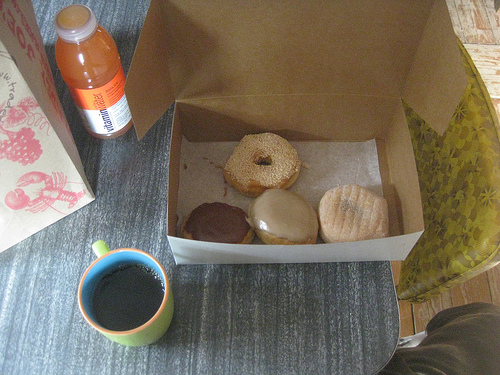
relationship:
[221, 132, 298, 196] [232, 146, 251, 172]
doughnut has sprinkles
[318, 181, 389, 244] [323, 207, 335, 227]
doughnuts has sugar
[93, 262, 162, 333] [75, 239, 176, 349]
coffee in a mug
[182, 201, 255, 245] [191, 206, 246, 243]
doughnut with chocolate icing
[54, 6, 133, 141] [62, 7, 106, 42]
bottle for drinking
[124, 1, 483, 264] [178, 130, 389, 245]
box with doughnuts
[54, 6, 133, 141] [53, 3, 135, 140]
bottle with drinking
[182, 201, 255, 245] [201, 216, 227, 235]
doughnut with chocolate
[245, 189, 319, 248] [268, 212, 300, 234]
donut covered with vanilla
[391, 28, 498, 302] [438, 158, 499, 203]
chair with design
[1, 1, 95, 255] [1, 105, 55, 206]
bag with design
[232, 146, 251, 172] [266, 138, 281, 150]
sprinkles of coconut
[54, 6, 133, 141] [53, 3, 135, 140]
bottle of drinking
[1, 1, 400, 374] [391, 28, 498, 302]
table with a chair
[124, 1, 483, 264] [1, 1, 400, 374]
box on table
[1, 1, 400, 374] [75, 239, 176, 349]
table has a mug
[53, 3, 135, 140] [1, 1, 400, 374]
drinking on a table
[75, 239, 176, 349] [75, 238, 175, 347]
mug has a drink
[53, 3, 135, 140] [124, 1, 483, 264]
drinking by a box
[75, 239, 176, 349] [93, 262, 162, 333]
mug has coffee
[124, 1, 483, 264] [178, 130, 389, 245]
box has doughnuts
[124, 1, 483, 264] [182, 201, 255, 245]
box has a doughnut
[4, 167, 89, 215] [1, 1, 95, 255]
lobster on bag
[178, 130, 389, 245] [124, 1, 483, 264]
doughnuts in a box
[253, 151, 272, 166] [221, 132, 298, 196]
hole in donut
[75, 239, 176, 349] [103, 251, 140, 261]
cup has blue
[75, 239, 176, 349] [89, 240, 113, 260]
mug has a handle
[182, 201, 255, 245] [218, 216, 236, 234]
doughnut has icing